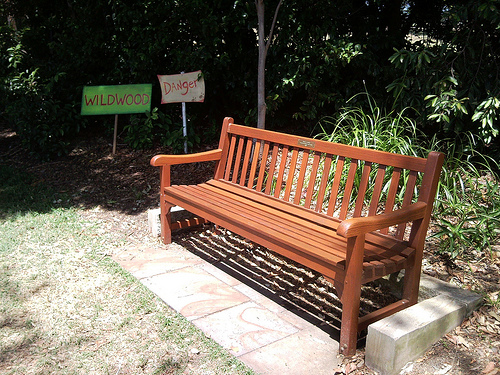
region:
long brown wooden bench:
[154, 133, 437, 300]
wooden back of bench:
[214, 126, 416, 222]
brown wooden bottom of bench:
[184, 176, 350, 283]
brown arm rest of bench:
[343, 200, 428, 242]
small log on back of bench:
[286, 137, 318, 154]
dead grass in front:
[17, 246, 113, 369]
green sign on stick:
[68, 82, 150, 120]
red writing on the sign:
[89, 90, 153, 115]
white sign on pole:
[153, 73, 200, 103]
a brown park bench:
[157, 116, 444, 354]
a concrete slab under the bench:
[111, 205, 477, 374]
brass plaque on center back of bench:
[294, 139, 317, 149]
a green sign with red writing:
[83, 85, 150, 159]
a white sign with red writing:
[160, 70, 205, 145]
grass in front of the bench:
[2, 180, 244, 373]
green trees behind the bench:
[5, 6, 494, 131]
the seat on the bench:
[167, 181, 414, 278]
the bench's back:
[216, 121, 440, 242]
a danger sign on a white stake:
[160, 68, 209, 150]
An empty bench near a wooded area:
[140, 101, 450, 367]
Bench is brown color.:
[158, 112, 430, 323]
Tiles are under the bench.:
[151, 226, 365, 374]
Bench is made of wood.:
[148, 122, 418, 284]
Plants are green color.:
[311, 74, 465, 154]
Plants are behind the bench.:
[292, 84, 483, 174]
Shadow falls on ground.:
[24, 109, 157, 276]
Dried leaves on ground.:
[436, 220, 498, 360]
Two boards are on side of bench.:
[73, 62, 202, 133]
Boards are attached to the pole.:
[69, 84, 206, 166]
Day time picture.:
[27, 86, 463, 328]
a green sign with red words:
[53, 53, 165, 165]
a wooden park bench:
[176, 132, 447, 316]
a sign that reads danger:
[159, 57, 204, 146]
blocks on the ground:
[122, 238, 277, 373]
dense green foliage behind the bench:
[282, 33, 494, 183]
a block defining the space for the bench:
[341, 280, 485, 372]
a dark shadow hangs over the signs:
[15, 87, 139, 211]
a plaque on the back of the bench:
[296, 130, 321, 159]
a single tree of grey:
[241, 10, 287, 160]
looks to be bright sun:
[394, 14, 459, 62]